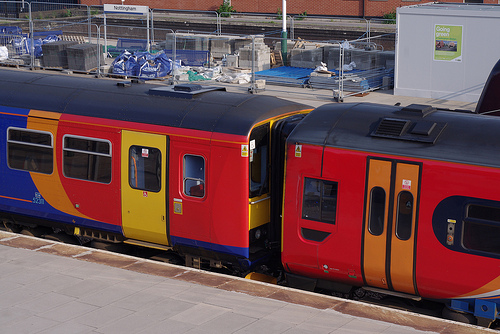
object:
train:
[0, 67, 500, 333]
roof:
[0, 71, 318, 136]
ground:
[0, 230, 500, 333]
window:
[125, 144, 163, 195]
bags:
[109, 49, 176, 82]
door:
[360, 154, 425, 296]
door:
[121, 128, 176, 247]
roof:
[80, 0, 473, 30]